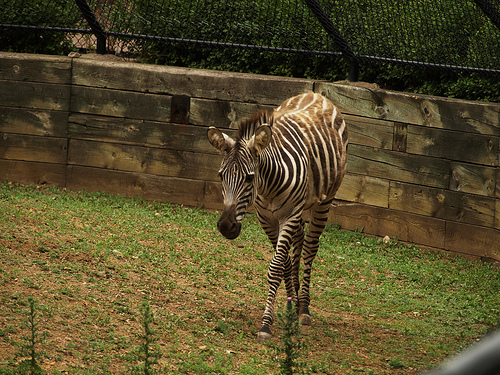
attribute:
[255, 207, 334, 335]
legs — four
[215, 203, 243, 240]
snout — brown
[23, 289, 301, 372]
trees — three, small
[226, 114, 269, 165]
mane — fur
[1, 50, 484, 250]
fence — brown color, wooden, block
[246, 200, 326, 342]
zebra legs — four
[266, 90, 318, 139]
back — zebra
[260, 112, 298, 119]
hairs — short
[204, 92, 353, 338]
zebra — striped, bending down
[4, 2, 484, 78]
fence — chainlink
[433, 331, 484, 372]
railing part — metal, fence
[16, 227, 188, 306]
patches — dirt, dry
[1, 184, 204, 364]
hill — small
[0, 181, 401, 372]
hill — small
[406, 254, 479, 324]
grass — green in color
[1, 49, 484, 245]
wall — wooden